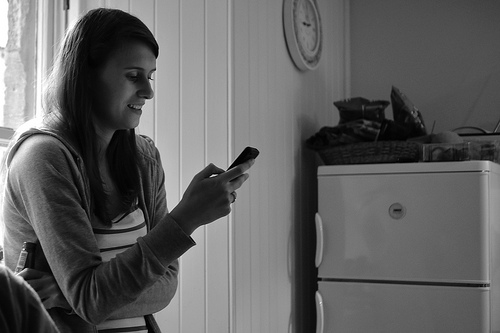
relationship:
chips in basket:
[306, 85, 428, 151] [313, 133, 424, 167]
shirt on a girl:
[88, 210, 176, 290] [37, 15, 252, 330]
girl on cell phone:
[2, 8, 255, 333] [223, 142, 263, 180]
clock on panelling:
[282, 0, 323, 73] [87, 0, 351, 333]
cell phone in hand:
[221, 138, 261, 179] [189, 152, 258, 234]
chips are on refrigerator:
[306, 85, 428, 151] [308, 160, 497, 330]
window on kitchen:
[9, 0, 50, 140] [0, 5, 496, 332]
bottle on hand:
[13, 242, 38, 275] [14, 265, 69, 306]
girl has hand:
[2, 8, 255, 333] [14, 265, 69, 306]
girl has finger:
[2, 8, 255, 333] [215, 157, 254, 181]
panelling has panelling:
[87, 0, 351, 333] [185, 4, 332, 328]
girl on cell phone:
[2, 8, 255, 333] [226, 147, 259, 182]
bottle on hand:
[0, 235, 42, 290] [25, 260, 70, 317]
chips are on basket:
[306, 85, 428, 151] [314, 137, 424, 165]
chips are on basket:
[328, 91, 392, 125] [314, 137, 424, 165]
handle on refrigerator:
[313, 289, 324, 332] [308, 160, 497, 330]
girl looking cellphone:
[2, 8, 255, 333] [228, 144, 250, 176]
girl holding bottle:
[2, 8, 255, 333] [13, 242, 38, 275]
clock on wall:
[282, 0, 323, 73] [226, 1, 352, 330]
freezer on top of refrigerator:
[316, 157, 499, 286] [308, 160, 497, 330]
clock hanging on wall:
[278, 0, 325, 73] [226, 1, 352, 330]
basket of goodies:
[317, 140, 423, 166] [339, 104, 404, 169]